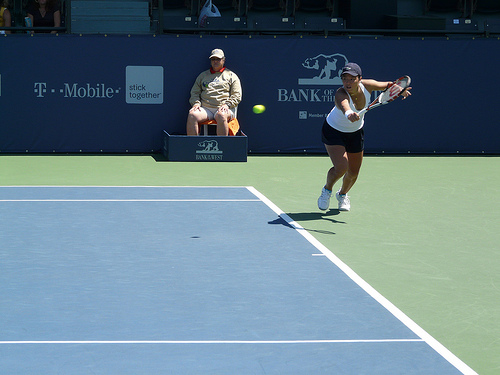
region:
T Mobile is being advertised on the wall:
[25, 59, 170, 107]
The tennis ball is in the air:
[244, 99, 273, 121]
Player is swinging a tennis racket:
[327, 56, 429, 129]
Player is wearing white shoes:
[302, 176, 367, 218]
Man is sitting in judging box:
[169, 43, 251, 165]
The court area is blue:
[2, 188, 258, 373]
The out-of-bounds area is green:
[362, 160, 499, 289]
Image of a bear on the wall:
[293, 46, 350, 87]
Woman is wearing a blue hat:
[338, 60, 366, 80]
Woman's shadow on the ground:
[264, 198, 362, 240]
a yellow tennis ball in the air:
[242, 97, 267, 115]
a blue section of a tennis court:
[113, 220, 186, 301]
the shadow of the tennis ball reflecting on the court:
[187, 230, 200, 241]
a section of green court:
[382, 201, 498, 251]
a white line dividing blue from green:
[335, 259, 373, 304]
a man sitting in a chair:
[182, 44, 233, 147]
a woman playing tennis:
[334, 56, 412, 206]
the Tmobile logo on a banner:
[28, 74, 118, 107]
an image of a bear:
[301, 54, 339, 81]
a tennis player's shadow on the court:
[265, 197, 337, 247]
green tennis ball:
[252, 103, 264, 114]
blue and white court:
[0, 187, 470, 373]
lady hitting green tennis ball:
[254, 62, 412, 215]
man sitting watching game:
[185, 42, 241, 134]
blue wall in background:
[2, 29, 499, 153]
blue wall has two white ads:
[3, 34, 498, 156]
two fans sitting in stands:
[0, 0, 67, 33]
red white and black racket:
[359, 75, 410, 115]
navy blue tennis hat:
[340, 62, 361, 77]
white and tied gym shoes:
[317, 189, 350, 211]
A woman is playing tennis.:
[296, 48, 426, 236]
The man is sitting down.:
[171, 35, 241, 137]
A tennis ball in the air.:
[240, 97, 275, 118]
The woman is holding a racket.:
[345, 70, 412, 125]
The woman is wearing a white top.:
[325, 66, 375, 126]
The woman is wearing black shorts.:
[295, 105, 375, 155]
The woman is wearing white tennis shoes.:
[300, 175, 357, 220]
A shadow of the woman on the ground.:
[245, 187, 357, 252]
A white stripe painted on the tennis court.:
[235, 175, 471, 371]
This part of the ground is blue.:
[25, 215, 275, 290]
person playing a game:
[296, 51, 414, 211]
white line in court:
[190, 311, 265, 371]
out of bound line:
[293, 233, 371, 308]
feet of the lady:
[294, 183, 372, 246]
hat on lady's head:
[318, 51, 375, 103]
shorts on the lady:
[320, 111, 388, 168]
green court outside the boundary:
[391, 187, 469, 252]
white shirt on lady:
[308, 81, 385, 147]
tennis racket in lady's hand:
[368, 63, 420, 127]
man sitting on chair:
[152, 36, 269, 146]